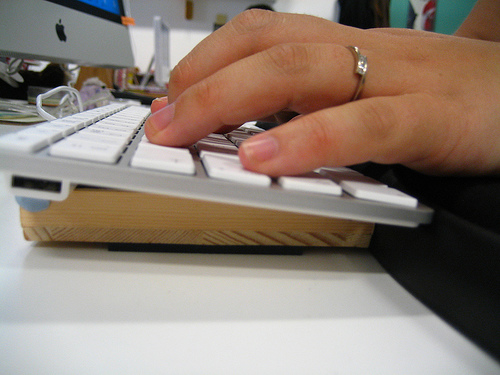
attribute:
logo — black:
[46, 18, 78, 43]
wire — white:
[35, 86, 82, 116]